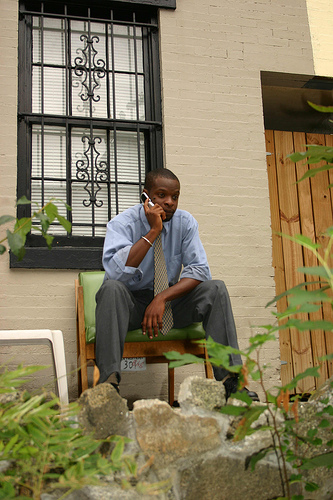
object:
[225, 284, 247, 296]
bricks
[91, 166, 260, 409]
man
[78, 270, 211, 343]
cushions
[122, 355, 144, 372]
sign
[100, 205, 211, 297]
shirt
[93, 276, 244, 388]
pants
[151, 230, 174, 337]
tie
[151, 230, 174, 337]
design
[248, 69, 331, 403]
door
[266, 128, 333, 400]
boards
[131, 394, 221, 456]
rocks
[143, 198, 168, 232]
hand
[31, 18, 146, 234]
blinds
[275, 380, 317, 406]
bracket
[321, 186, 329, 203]
hole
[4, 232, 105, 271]
sill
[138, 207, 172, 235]
neck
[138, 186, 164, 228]
phone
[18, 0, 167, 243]
grate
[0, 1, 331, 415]
wall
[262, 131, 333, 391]
fence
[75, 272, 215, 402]
chair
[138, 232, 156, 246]
bracelet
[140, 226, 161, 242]
wrist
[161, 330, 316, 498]
plants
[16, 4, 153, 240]
window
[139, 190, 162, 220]
cellphone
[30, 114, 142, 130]
bars